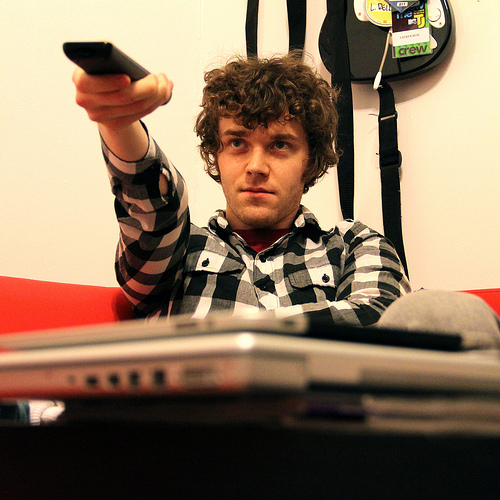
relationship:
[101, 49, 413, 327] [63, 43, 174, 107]
man holding control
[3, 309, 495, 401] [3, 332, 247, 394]
laptop has side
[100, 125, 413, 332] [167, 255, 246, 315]
shirt has pocket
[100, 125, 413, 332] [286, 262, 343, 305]
shirt has pocket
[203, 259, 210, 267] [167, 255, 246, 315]
button on top of pocket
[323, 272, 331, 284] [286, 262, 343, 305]
button on top of pocket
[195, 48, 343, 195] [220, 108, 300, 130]
hair on top of forehead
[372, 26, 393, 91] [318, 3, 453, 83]
bar off guitar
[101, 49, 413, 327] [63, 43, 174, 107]
man using control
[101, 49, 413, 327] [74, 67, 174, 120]
man has hand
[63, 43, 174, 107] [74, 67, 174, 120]
control inside hand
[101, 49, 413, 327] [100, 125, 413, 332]
man has shirt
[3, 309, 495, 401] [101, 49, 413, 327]
laptop in front of man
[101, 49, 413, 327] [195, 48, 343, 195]
man has hair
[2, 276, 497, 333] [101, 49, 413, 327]
couch underneath man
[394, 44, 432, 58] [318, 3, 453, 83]
paper on top of guitar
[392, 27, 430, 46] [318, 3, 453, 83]
paper on top of guitar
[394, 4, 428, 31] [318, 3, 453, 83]
paper on top of guitar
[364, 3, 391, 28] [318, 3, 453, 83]
paper on top of guitar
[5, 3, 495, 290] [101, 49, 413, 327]
wall behind man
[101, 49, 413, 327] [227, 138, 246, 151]
man has eye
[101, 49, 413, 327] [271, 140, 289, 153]
man has eye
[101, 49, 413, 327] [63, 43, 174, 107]
man has control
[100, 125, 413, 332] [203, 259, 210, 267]
shirt has button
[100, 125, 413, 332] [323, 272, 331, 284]
shirt has button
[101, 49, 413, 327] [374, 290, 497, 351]
man has pants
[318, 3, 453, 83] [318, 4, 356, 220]
guitar has strap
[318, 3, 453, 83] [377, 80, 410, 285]
guitar has strap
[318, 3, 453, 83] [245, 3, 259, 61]
guitar has strap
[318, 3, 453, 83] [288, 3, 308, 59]
guitar has strap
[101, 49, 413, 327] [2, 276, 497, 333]
man sitting on top of couch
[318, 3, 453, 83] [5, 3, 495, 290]
guitar on top of wall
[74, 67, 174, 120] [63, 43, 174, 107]
hand has control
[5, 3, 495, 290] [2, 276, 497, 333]
wall behind couch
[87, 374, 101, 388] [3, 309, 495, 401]
hole inside of laptop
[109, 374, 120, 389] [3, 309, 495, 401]
hole inside of laptop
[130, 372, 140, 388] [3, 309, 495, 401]
hole inside of laptop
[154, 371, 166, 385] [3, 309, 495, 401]
hole inside of laptop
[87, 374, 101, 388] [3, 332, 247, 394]
hole inside of side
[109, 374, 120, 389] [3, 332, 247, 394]
hole inside of side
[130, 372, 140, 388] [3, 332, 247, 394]
hole inside of side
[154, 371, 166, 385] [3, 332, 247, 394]
hole inside of side